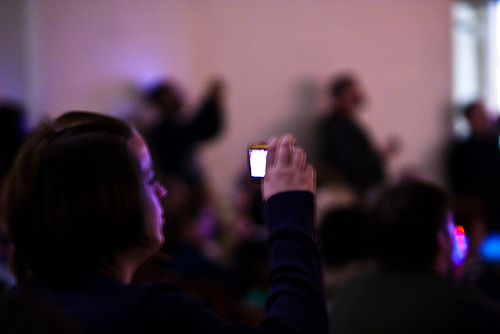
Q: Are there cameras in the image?
A: Yes, there is a camera.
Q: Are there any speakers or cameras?
A: Yes, there is a camera.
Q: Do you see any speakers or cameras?
A: Yes, there is a camera.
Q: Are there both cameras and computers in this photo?
A: No, there is a camera but no computers.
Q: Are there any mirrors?
A: No, there are no mirrors.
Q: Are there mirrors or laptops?
A: No, there are no mirrors or laptops.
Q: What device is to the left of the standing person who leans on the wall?
A: The device is a camera.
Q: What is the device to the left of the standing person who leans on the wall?
A: The device is a camera.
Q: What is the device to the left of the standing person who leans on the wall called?
A: The device is a camera.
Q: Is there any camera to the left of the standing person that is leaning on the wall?
A: Yes, there is a camera to the left of the person.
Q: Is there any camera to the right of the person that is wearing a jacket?
A: No, the camera is to the left of the person.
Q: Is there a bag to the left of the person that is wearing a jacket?
A: No, there is a camera to the left of the person.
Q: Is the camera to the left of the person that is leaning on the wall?
A: Yes, the camera is to the left of the person.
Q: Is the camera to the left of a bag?
A: No, the camera is to the left of the person.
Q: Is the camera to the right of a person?
A: No, the camera is to the left of a person.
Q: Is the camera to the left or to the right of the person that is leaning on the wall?
A: The camera is to the left of the person.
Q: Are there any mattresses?
A: No, there are no mattresses.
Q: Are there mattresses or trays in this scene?
A: No, there are no mattresses or trays.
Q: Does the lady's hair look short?
A: Yes, the hair is short.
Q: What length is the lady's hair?
A: The hair is short.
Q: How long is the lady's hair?
A: The hair is short.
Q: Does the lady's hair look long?
A: No, the hair is short.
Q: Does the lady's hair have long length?
A: No, the hair is short.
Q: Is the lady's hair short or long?
A: The hair is short.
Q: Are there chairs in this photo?
A: No, there are no chairs.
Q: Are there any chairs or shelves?
A: No, there are no chairs or shelves.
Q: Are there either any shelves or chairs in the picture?
A: No, there are no chairs or shelves.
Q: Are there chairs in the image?
A: No, there are no chairs.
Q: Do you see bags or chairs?
A: No, there are no chairs or bags.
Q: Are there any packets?
A: No, there are no packets.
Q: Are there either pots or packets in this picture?
A: No, there are no packets or pots.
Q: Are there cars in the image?
A: No, there are no cars.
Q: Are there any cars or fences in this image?
A: No, there are no cars or fences.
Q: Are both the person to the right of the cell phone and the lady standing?
A: Yes, both the person and the lady are standing.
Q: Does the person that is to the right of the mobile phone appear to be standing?
A: Yes, the person is standing.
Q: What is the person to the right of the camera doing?
A: The person is standing.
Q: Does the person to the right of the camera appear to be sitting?
A: No, the person is standing.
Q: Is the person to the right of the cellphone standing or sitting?
A: The person is standing.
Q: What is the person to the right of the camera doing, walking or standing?
A: The person is standing.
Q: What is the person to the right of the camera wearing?
A: The person is wearing a jacket.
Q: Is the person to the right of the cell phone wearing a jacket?
A: Yes, the person is wearing a jacket.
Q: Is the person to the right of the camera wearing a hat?
A: No, the person is wearing a jacket.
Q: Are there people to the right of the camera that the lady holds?
A: Yes, there is a person to the right of the camera.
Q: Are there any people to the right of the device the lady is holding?
A: Yes, there is a person to the right of the camera.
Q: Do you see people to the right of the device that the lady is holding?
A: Yes, there is a person to the right of the camera.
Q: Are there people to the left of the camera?
A: No, the person is to the right of the camera.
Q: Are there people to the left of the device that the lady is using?
A: No, the person is to the right of the camera.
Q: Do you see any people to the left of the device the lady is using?
A: No, the person is to the right of the camera.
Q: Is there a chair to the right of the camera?
A: No, there is a person to the right of the camera.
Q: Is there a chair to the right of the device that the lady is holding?
A: No, there is a person to the right of the camera.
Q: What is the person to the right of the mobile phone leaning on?
A: The person is leaning on the wall.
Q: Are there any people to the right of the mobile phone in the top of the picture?
A: Yes, there is a person to the right of the cell phone.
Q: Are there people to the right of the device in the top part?
A: Yes, there is a person to the right of the cell phone.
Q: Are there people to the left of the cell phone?
A: No, the person is to the right of the cell phone.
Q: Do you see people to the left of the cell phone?
A: No, the person is to the right of the cell phone.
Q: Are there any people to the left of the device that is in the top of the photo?
A: No, the person is to the right of the cell phone.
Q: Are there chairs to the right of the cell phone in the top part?
A: No, there is a person to the right of the cell phone.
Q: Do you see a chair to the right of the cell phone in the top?
A: No, there is a person to the right of the cell phone.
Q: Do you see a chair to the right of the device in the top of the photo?
A: No, there is a person to the right of the cell phone.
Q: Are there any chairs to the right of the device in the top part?
A: No, there is a person to the right of the cell phone.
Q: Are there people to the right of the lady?
A: Yes, there is a person to the right of the lady.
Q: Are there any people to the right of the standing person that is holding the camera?
A: Yes, there is a person to the right of the lady.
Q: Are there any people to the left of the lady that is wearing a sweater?
A: No, the person is to the right of the lady.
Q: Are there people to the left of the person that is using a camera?
A: No, the person is to the right of the lady.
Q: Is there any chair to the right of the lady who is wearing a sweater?
A: No, there is a person to the right of the lady.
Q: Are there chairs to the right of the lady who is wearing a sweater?
A: No, there is a person to the right of the lady.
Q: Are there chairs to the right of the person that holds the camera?
A: No, there is a person to the right of the lady.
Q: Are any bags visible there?
A: No, there are no bags.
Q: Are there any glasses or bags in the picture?
A: No, there are no bags or glasses.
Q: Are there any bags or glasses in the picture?
A: No, there are no bags or glasses.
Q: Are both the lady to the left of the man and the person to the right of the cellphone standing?
A: Yes, both the lady and the person are standing.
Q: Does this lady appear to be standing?
A: Yes, the lady is standing.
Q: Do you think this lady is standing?
A: Yes, the lady is standing.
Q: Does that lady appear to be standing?
A: Yes, the lady is standing.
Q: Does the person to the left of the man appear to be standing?
A: Yes, the lady is standing.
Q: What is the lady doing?
A: The lady is standing.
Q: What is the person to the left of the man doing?
A: The lady is standing.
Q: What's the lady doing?
A: The lady is standing.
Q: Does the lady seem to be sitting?
A: No, the lady is standing.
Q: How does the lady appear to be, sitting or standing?
A: The lady is standing.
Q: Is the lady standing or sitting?
A: The lady is standing.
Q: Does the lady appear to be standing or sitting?
A: The lady is standing.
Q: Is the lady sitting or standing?
A: The lady is standing.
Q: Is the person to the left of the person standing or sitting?
A: The lady is standing.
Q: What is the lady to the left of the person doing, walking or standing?
A: The lady is standing.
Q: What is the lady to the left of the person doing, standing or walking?
A: The lady is standing.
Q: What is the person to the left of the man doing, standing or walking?
A: The lady is standing.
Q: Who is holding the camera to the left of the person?
A: The lady is holding the camera.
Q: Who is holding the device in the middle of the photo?
A: The lady is holding the camera.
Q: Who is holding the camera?
A: The lady is holding the camera.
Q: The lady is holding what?
A: The lady is holding the camera.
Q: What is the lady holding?
A: The lady is holding the camera.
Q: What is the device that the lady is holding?
A: The device is a camera.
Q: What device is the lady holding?
A: The lady is holding the camera.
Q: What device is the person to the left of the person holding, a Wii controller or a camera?
A: The lady is holding a camera.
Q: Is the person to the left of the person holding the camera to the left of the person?
A: Yes, the lady is holding the camera.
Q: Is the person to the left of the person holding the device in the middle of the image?
A: Yes, the lady is holding the camera.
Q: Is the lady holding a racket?
A: No, the lady is holding the camera.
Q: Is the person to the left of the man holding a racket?
A: No, the lady is holding the camera.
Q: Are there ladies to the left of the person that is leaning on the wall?
A: Yes, there is a lady to the left of the person.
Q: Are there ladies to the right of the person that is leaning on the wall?
A: No, the lady is to the left of the person.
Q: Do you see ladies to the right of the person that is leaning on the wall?
A: No, the lady is to the left of the person.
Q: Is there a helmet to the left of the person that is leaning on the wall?
A: No, there is a lady to the left of the person.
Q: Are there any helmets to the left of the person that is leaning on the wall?
A: No, there is a lady to the left of the person.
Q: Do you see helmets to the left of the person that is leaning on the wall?
A: No, there is a lady to the left of the person.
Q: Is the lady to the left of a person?
A: Yes, the lady is to the left of a person.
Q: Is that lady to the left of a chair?
A: No, the lady is to the left of a person.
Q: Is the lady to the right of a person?
A: No, the lady is to the left of a person.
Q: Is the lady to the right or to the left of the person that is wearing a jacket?
A: The lady is to the left of the person.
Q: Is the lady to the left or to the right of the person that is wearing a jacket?
A: The lady is to the left of the person.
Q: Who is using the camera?
A: The lady is using the camera.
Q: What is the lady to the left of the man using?
A: The lady is using a camera.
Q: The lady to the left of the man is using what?
A: The lady is using a camera.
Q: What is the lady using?
A: The lady is using a camera.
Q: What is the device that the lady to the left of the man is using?
A: The device is a camera.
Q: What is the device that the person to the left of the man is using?
A: The device is a camera.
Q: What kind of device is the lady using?
A: The lady is using a camera.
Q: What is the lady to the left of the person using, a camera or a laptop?
A: The lady is using a camera.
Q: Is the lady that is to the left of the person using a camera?
A: Yes, the lady is using a camera.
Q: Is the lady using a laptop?
A: No, the lady is using a camera.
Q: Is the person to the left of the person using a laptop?
A: No, the lady is using a camera.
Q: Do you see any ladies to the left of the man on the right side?
A: Yes, there is a lady to the left of the man.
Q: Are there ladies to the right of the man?
A: No, the lady is to the left of the man.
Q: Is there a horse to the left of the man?
A: No, there is a lady to the left of the man.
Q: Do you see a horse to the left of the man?
A: No, there is a lady to the left of the man.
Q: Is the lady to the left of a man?
A: Yes, the lady is to the left of a man.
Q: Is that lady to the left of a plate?
A: No, the lady is to the left of a man.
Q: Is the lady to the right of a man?
A: No, the lady is to the left of a man.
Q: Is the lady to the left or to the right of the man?
A: The lady is to the left of the man.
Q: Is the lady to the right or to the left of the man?
A: The lady is to the left of the man.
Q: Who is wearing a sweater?
A: The lady is wearing a sweater.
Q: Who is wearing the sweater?
A: The lady is wearing a sweater.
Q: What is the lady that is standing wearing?
A: The lady is wearing a sweater.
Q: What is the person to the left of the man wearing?
A: The lady is wearing a sweater.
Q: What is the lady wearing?
A: The lady is wearing a sweater.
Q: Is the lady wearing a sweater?
A: Yes, the lady is wearing a sweater.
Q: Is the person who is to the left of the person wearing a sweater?
A: Yes, the lady is wearing a sweater.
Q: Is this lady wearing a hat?
A: No, the lady is wearing a sweater.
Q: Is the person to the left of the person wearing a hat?
A: No, the lady is wearing a sweater.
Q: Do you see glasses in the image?
A: No, there are no glasses.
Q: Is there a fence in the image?
A: No, there are no fences.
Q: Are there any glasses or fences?
A: No, there are no fences or glasses.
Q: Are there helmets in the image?
A: No, there are no helmets.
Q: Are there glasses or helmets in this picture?
A: No, there are no helmets or glasses.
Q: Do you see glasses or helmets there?
A: No, there are no helmets or glasses.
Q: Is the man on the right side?
A: Yes, the man is on the right of the image.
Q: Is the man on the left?
A: No, the man is on the right of the image.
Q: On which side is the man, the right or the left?
A: The man is on the right of the image.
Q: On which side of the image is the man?
A: The man is on the right of the image.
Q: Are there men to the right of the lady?
A: Yes, there is a man to the right of the lady.